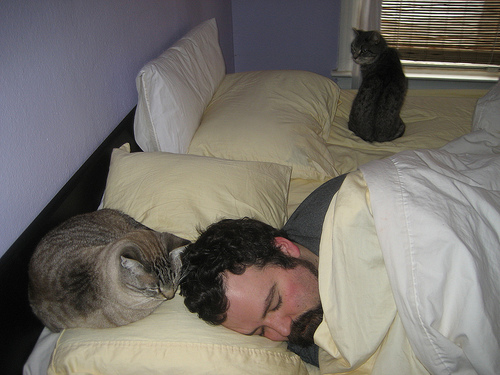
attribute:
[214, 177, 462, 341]
man — asleep, chubby, wide, alseep, sleeping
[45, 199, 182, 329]
cat — black, gray, grey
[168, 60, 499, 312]
bed — yellow, large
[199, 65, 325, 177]
pillow — white, yellow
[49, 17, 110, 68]
wall — blue